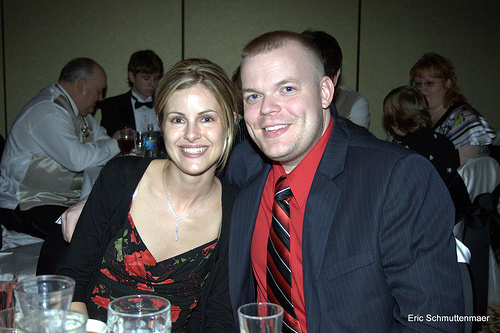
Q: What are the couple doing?
A: Smiling.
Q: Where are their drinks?
A: On the table.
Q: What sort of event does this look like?
A: A wedding.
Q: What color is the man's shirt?
A: Red.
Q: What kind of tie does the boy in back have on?
A: Bow.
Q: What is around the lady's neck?
A: A necklace.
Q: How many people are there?
A: 8.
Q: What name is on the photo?
A: Eric Schmutlenmaer.